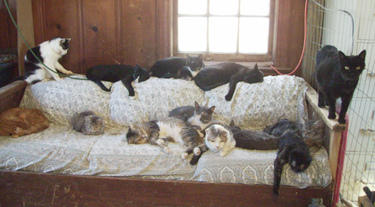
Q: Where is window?
A: In background.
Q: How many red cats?
A: One.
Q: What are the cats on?
A: A couch.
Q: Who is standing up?
A: A black cat.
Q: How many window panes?
A: Six.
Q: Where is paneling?
A: On back wall.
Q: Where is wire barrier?
A: On right.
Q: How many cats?
A: Fourteen.